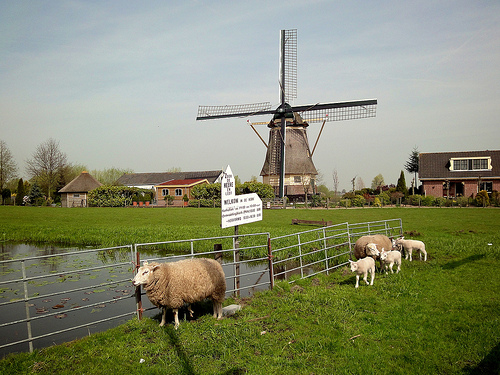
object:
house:
[417, 145, 499, 198]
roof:
[417, 149, 499, 181]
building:
[153, 179, 210, 206]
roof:
[112, 170, 223, 186]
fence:
[1, 218, 404, 353]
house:
[112, 169, 225, 206]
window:
[477, 182, 493, 200]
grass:
[233, 283, 497, 373]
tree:
[29, 138, 71, 205]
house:
[59, 171, 103, 208]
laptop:
[131, 258, 226, 328]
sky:
[0, 0, 500, 193]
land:
[128, 207, 192, 230]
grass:
[1, 204, 500, 374]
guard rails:
[233, 232, 274, 300]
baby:
[380, 248, 402, 275]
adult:
[132, 257, 226, 329]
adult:
[353, 234, 392, 272]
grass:
[279, 305, 419, 362]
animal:
[348, 257, 375, 288]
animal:
[395, 236, 428, 261]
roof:
[153, 178, 210, 187]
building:
[112, 170, 225, 207]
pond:
[1, 241, 338, 353]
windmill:
[196, 28, 377, 202]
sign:
[221, 164, 263, 229]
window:
[448, 155, 492, 172]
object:
[196, 28, 377, 203]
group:
[348, 234, 427, 287]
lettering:
[221, 197, 261, 223]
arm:
[278, 28, 298, 108]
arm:
[289, 99, 376, 123]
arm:
[268, 119, 282, 209]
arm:
[195, 101, 274, 120]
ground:
[0, 206, 499, 374]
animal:
[132, 258, 227, 328]